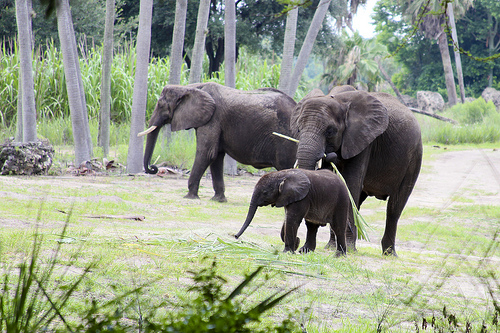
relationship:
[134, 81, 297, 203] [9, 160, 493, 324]
adults in field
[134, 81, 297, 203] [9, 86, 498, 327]
adults in field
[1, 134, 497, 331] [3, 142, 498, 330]
grass on ground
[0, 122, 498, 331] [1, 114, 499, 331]
leaves on plant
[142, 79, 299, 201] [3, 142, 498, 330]
adults walking across ground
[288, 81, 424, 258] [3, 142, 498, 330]
adults walking across ground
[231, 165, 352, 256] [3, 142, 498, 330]
baby walking across ground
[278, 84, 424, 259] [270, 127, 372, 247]
adults carrying stalk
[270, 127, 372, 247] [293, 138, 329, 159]
stalk in mouth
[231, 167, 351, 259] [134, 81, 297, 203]
baby walking in front of adults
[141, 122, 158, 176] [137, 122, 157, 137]
trunk below tusk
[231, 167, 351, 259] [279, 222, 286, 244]
baby has knee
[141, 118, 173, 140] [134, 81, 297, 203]
tusk on adults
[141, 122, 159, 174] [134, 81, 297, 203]
trunk on adults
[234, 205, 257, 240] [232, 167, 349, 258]
trunk on elephant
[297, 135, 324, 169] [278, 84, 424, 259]
trunk on adults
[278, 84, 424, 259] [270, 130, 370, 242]
adults carrying plant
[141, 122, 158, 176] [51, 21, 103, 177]
trunk on tree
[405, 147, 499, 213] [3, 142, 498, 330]
dirt on ground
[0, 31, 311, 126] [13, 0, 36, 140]
bushes behind tree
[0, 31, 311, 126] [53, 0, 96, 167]
bushes behind tree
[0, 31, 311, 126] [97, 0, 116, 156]
bushes behind tree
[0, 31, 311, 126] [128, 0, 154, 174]
bushes behind tree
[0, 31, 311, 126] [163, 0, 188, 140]
bushes behind tree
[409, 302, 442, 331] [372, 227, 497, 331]
branch on bush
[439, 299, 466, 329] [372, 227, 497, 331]
branch on bush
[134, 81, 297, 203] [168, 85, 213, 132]
adults has ear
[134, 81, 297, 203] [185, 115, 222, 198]
adults has leg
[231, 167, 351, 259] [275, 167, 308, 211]
baby has ear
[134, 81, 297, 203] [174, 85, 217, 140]
adults has ear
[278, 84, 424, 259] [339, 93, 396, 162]
adults has ear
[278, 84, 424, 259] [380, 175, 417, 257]
adults has leg